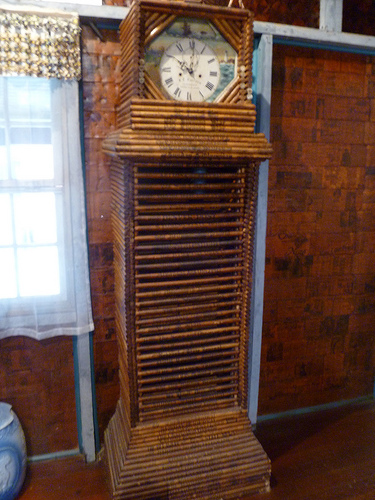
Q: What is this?
A: A clock.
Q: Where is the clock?
A: On the floor.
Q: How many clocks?
A: 1.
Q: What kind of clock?
A: Antique.